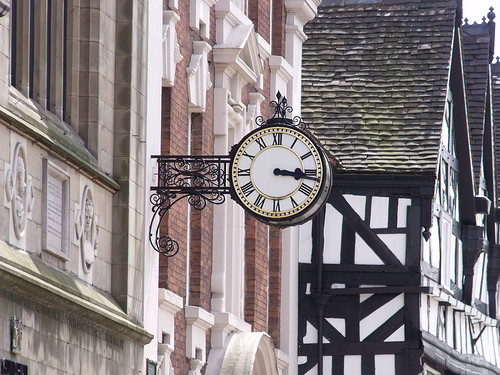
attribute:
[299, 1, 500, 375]
building — black, white, medieval, old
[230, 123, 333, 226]
clock — round, white, decorative, attached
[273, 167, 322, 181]
hands — black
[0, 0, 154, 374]
stone — carved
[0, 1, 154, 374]
building — grey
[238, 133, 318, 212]
roman numbers — black, roman numerals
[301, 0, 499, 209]
roof — black, green, dented